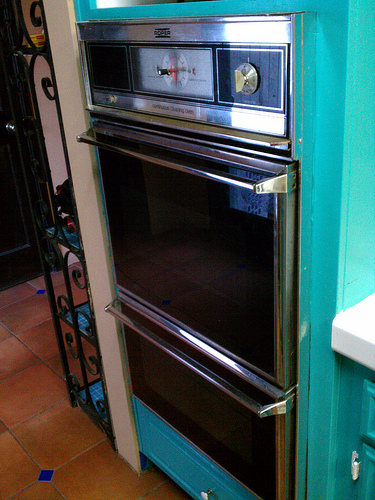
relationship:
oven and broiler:
[88, 116, 323, 382] [107, 307, 293, 499]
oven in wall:
[88, 116, 323, 382] [81, 5, 369, 499]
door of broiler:
[101, 314, 286, 498] [107, 307, 293, 499]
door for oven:
[90, 127, 297, 386] [88, 116, 323, 382]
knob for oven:
[230, 57, 262, 95] [88, 116, 323, 382]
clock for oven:
[143, 51, 209, 94] [88, 116, 323, 382]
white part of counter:
[358, 312, 374, 335] [324, 294, 372, 391]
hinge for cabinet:
[349, 449, 361, 483] [339, 363, 375, 498]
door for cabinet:
[359, 447, 374, 500] [339, 363, 375, 498]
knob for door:
[5, 115, 19, 132] [3, 4, 56, 291]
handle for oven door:
[79, 128, 287, 199] [90, 127, 297, 386]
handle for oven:
[79, 128, 287, 199] [88, 116, 323, 382]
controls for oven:
[79, 25, 286, 128] [88, 116, 323, 382]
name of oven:
[152, 27, 175, 40] [88, 116, 323, 382]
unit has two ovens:
[74, 20, 305, 498] [88, 113, 292, 497]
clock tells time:
[143, 51, 209, 94] [170, 56, 179, 87]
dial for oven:
[230, 57, 262, 95] [88, 116, 323, 382]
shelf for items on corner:
[13, 1, 111, 462] [51, 1, 115, 432]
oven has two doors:
[88, 116, 323, 382] [94, 130, 286, 487]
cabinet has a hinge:
[339, 363, 375, 498] [349, 449, 361, 483]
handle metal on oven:
[79, 128, 287, 199] [88, 116, 323, 382]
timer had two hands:
[156, 53, 196, 89] [170, 56, 179, 87]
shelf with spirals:
[13, 1, 111, 462] [46, 241, 102, 383]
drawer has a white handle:
[133, 408, 265, 499] [197, 485, 211, 499]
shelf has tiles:
[13, 1, 111, 462] [66, 300, 93, 334]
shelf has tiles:
[13, 1, 111, 462] [44, 215, 78, 252]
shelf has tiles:
[13, 1, 111, 462] [81, 374, 107, 416]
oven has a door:
[88, 116, 323, 382] [90, 127, 297, 386]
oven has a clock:
[88, 116, 323, 382] [143, 51, 209, 94]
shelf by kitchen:
[13, 1, 111, 462] [4, 0, 373, 499]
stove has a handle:
[88, 116, 323, 382] [79, 128, 287, 199]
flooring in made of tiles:
[0, 266, 189, 499] [16, 395, 104, 478]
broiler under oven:
[107, 307, 293, 499] [88, 116, 323, 382]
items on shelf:
[49, 183, 77, 244] [13, 1, 111, 462]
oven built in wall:
[88, 116, 323, 382] [81, 5, 369, 499]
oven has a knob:
[88, 116, 323, 382] [230, 57, 262, 95]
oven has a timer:
[88, 116, 323, 382] [156, 53, 196, 89]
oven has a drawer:
[88, 116, 323, 382] [133, 408, 265, 499]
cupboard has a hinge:
[339, 363, 375, 498] [349, 449, 361, 483]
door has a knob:
[3, 4, 56, 291] [5, 115, 19, 132]